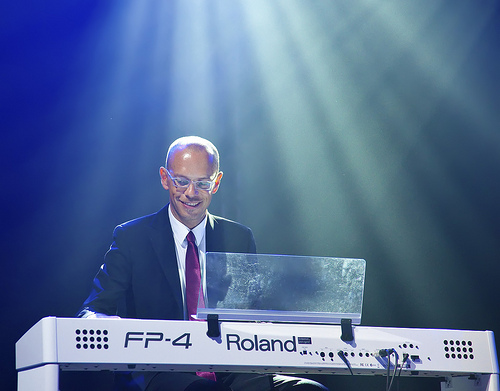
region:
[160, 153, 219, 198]
glasses on a man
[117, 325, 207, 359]
black writing on a keyboard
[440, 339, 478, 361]
black dots ona keyboard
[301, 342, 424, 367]
wires plugged into a keyboard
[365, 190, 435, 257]
light shinging through the darkness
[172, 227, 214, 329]
maroon tie on a man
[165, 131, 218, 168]
light reflecting on a man's head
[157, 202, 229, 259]
white collar on a man's shirt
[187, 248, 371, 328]
lear music holder on a keyboard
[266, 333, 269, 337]
edge of a board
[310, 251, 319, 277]
part of a board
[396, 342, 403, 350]
part of a piano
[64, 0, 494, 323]
Lights shining done on a man.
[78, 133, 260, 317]
Man sitting at a table.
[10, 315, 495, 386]
A grey colored table.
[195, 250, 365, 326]
A plastic screen on a grey table.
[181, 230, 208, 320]
A purple tie.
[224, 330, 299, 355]
The word Roland on a grey table.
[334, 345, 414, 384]
Cords connected to a table.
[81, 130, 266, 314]
A man smiling.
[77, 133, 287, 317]
A man looking down.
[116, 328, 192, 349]
The letters FP-4 on a grey organ.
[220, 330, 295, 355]
The word Roland on the front of a grey organ.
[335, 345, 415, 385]
Black cords connected to an organ.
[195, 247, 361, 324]
A plastic holder on an organ.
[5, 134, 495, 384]
A man playing an organ.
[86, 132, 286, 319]
A man looking down at the organ.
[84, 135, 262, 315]
A man with a smile.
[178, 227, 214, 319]
A purple tie.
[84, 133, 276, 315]
Man in a blue suit.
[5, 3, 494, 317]
Lights shining down on a man.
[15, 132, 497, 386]
Man in the spotlight.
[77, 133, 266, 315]
Bald man sitting down.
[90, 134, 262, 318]
Bald man wearing a suit and tie.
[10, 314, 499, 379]
Grey table with cords connected to the back.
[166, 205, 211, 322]
White dress shirt.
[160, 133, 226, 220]
Man wearing eyeglasses.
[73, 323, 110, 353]
Black dots on a table.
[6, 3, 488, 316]
Bright lights shining down on a man.